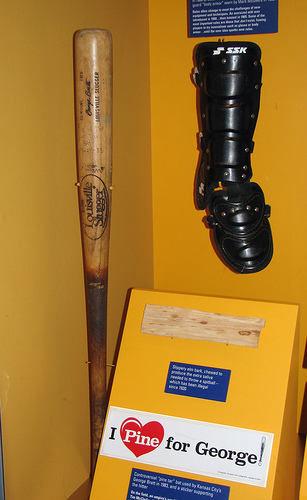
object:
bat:
[58, 40, 108, 225]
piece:
[43, 42, 84, 83]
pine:
[64, 31, 141, 166]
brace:
[164, 54, 261, 210]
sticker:
[112, 387, 300, 475]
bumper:
[59, 357, 299, 487]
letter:
[116, 423, 141, 458]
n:
[133, 427, 155, 449]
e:
[141, 437, 163, 458]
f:
[157, 431, 172, 459]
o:
[175, 442, 181, 460]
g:
[192, 435, 213, 463]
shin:
[169, 82, 285, 180]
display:
[110, 328, 262, 492]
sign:
[173, 0, 303, 32]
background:
[178, 406, 237, 450]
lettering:
[164, 358, 219, 394]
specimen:
[54, 25, 158, 310]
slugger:
[66, 170, 145, 253]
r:
[180, 437, 197, 469]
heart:
[108, 401, 166, 478]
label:
[149, 341, 300, 436]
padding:
[163, 54, 305, 254]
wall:
[140, 62, 271, 244]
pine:
[113, 413, 177, 464]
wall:
[7, 100, 69, 280]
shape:
[101, 412, 195, 482]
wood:
[0, 40, 144, 374]